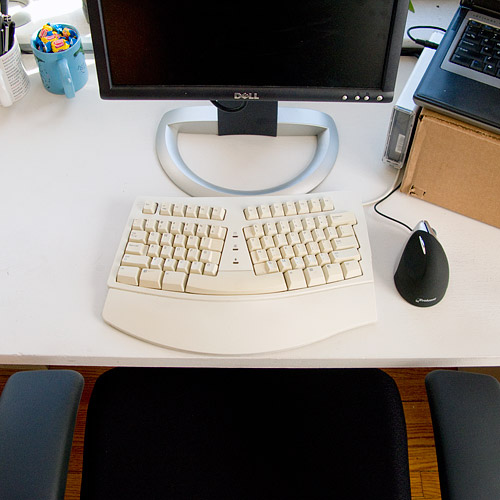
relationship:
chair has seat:
[2, 364, 499, 498] [78, 366, 415, 499]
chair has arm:
[2, 364, 499, 498] [418, 368, 498, 499]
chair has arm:
[2, 364, 499, 498] [2, 364, 92, 498]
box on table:
[394, 99, 500, 227] [1, 1, 500, 371]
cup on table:
[27, 21, 94, 101] [1, 1, 500, 371]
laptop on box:
[406, 2, 499, 145] [394, 99, 500, 227]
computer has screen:
[79, 1, 419, 201] [101, 2, 401, 97]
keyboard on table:
[97, 186, 386, 362] [1, 1, 500, 371]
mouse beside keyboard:
[384, 222, 455, 314] [97, 186, 386, 362]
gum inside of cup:
[31, 22, 77, 55] [27, 21, 94, 101]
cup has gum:
[27, 21, 94, 101] [31, 22, 77, 55]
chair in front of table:
[2, 364, 499, 498] [1, 1, 500, 371]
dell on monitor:
[228, 89, 266, 103] [79, 0, 417, 202]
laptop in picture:
[406, 2, 499, 145] [1, 0, 494, 497]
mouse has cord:
[384, 222, 455, 314] [372, 176, 418, 237]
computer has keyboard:
[79, 1, 419, 201] [97, 186, 386, 362]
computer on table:
[79, 1, 419, 201] [1, 1, 500, 371]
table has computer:
[1, 1, 500, 371] [79, 1, 419, 201]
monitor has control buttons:
[79, 0, 417, 202] [335, 91, 389, 107]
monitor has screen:
[79, 0, 417, 202] [101, 2, 401, 97]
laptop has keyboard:
[406, 2, 499, 145] [449, 17, 500, 84]